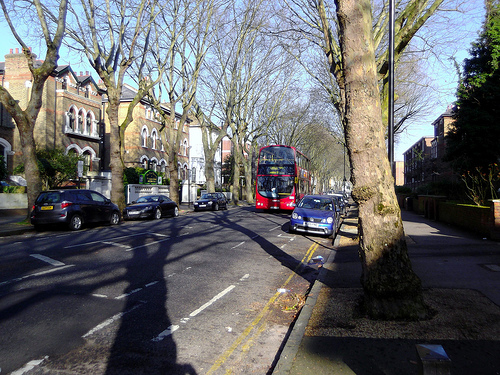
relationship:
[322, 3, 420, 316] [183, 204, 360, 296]
tree has shadow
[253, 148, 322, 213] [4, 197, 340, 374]
bus on road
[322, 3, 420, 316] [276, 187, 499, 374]
tree planted in sidewalk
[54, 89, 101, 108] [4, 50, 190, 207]
stripe on building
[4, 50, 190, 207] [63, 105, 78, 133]
building has window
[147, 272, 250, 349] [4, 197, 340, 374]
line painted on road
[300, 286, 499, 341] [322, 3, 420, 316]
gravel around tree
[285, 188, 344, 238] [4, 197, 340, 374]
car parked on road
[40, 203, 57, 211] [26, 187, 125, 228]
license plate on back of car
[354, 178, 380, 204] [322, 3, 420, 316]
moss growing on tree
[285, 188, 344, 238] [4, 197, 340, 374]
car sitting on road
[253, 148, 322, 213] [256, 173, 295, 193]
bus has windshield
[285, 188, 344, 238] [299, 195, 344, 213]
car has windshield